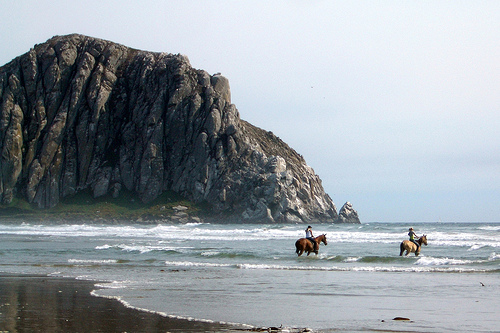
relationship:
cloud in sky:
[354, 81, 434, 133] [0, 1, 498, 222]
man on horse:
[305, 226, 317, 251] [292, 233, 329, 258]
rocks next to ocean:
[0, 33, 361, 224] [0, 220, 500, 331]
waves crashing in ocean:
[0, 217, 500, 277] [0, 220, 500, 331]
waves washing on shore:
[0, 225, 499, 331] [3, 245, 313, 330]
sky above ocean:
[0, 1, 498, 222] [8, 218, 496, 263]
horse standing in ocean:
[295, 233, 328, 257] [89, 217, 253, 281]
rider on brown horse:
[407, 225, 416, 246] [400, 234, 428, 257]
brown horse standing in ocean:
[400, 234, 428, 257] [1, 221, 498, 272]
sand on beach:
[3, 273, 285, 330] [1, 244, 496, 330]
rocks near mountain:
[171, 204, 202, 223] [7, 26, 359, 221]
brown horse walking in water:
[400, 234, 428, 257] [0, 221, 499, 331]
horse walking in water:
[295, 233, 328, 257] [0, 221, 499, 331]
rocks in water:
[341, 202, 356, 225] [0, 221, 499, 331]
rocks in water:
[168, 201, 202, 225] [0, 221, 499, 331]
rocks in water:
[0, 31, 362, 221] [0, 221, 499, 331]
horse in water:
[293, 235, 350, 253] [34, 214, 484, 317]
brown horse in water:
[400, 234, 428, 257] [34, 214, 484, 317]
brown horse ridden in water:
[390, 235, 436, 269] [386, 255, 488, 310]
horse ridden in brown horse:
[295, 233, 328, 257] [400, 234, 428, 257]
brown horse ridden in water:
[400, 234, 428, 257] [0, 221, 499, 331]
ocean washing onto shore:
[0, 223, 499, 333] [14, 219, 352, 315]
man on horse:
[305, 226, 317, 251] [290, 231, 325, 261]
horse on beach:
[295, 233, 328, 257] [15, 200, 456, 315]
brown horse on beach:
[400, 234, 428, 257] [15, 200, 456, 315]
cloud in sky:
[90, 0, 468, 141] [0, 1, 498, 222]